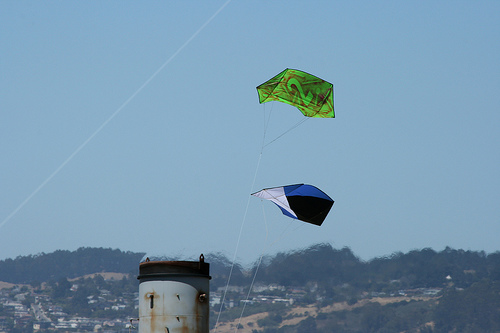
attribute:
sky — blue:
[47, 31, 216, 134]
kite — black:
[251, 171, 337, 228]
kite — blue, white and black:
[243, 181, 338, 231]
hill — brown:
[210, 293, 442, 331]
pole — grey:
[138, 283, 224, 330]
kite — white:
[248, 169, 345, 234]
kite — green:
[241, 61, 353, 133]